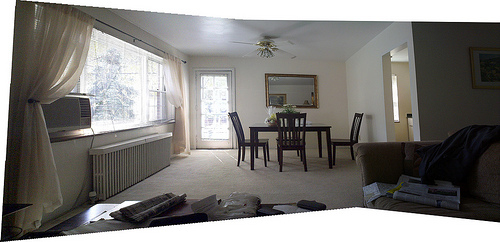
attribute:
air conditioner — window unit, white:
[41, 92, 91, 133]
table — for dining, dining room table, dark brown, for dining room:
[249, 125, 333, 170]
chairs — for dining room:
[229, 112, 364, 172]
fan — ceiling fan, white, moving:
[230, 36, 295, 62]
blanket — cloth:
[416, 125, 500, 185]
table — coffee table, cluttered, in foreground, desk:
[43, 201, 316, 237]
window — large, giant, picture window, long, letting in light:
[34, 3, 175, 143]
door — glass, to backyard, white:
[196, 71, 233, 149]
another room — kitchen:
[391, 48, 415, 142]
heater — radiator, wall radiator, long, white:
[88, 132, 172, 205]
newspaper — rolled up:
[110, 188, 187, 223]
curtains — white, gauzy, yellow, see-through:
[2, 0, 95, 231]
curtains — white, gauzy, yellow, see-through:
[164, 52, 187, 156]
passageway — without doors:
[382, 42, 414, 142]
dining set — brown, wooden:
[228, 111, 364, 172]